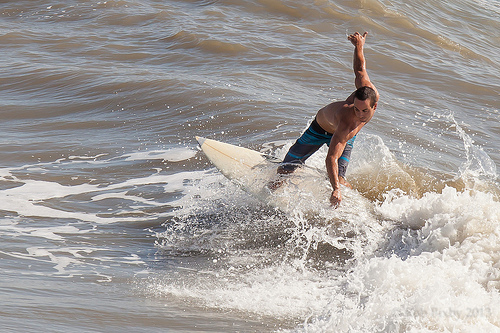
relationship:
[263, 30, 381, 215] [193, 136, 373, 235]
man on board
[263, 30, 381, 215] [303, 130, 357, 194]
man bending over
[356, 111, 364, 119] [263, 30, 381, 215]
nose of a man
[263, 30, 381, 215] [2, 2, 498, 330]
man in ocean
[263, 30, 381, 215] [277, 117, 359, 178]
man wearing shorts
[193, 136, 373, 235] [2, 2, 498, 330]
board coming out water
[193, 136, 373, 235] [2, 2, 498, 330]
board splashing water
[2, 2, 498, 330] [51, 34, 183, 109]
water dirty grey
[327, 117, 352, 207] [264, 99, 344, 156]
arms are out sides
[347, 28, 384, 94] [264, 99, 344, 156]
arms are out sides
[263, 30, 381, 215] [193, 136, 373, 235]
man riding board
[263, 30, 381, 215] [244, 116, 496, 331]
man surfing on wave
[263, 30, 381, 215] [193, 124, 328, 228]
man surfing on board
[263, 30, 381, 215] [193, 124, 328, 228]
man riding short board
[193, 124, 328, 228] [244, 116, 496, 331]
board in wave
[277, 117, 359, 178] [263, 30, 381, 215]
shorts on man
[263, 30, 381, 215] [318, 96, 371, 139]
man surfing shirt off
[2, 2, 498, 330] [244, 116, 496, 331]
water from wave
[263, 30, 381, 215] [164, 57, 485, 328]
person surfing ocean waves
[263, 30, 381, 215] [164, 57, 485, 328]
person surfing waves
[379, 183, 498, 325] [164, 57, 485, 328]
rough ocean waves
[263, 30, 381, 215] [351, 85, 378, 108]
person with dark hair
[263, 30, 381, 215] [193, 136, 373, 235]
man twisisting for board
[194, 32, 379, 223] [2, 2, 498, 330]
man in warm water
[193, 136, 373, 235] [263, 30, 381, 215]
board ridden by man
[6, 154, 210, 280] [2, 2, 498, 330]
foam on water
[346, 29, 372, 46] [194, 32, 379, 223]
left hand of man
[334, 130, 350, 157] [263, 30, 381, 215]
right bicep of surfer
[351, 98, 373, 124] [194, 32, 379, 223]
face of man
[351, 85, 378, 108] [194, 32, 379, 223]
hair of man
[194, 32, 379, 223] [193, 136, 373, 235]
man twisiting for board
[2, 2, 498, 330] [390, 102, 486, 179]
water in air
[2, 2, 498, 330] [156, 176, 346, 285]
water in air